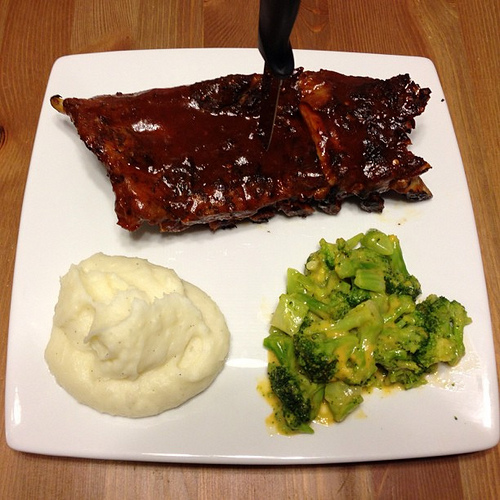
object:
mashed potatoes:
[44, 252, 231, 420]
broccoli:
[354, 266, 386, 294]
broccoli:
[293, 299, 382, 387]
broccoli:
[414, 295, 472, 368]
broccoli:
[269, 294, 310, 338]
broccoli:
[267, 366, 327, 431]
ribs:
[41, 65, 433, 234]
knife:
[259, 0, 302, 152]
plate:
[5, 46, 499, 468]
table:
[1, 0, 500, 499]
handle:
[258, 0, 301, 76]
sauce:
[101, 69, 368, 229]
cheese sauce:
[256, 379, 373, 435]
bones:
[382, 178, 434, 203]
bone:
[49, 95, 66, 114]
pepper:
[116, 340, 122, 346]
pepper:
[178, 371, 183, 378]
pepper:
[135, 261, 142, 267]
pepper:
[73, 328, 78, 333]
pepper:
[90, 368, 94, 373]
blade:
[258, 60, 285, 151]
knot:
[300, 4, 332, 33]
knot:
[110, 36, 143, 51]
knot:
[0, 128, 4, 147]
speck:
[441, 97, 446, 102]